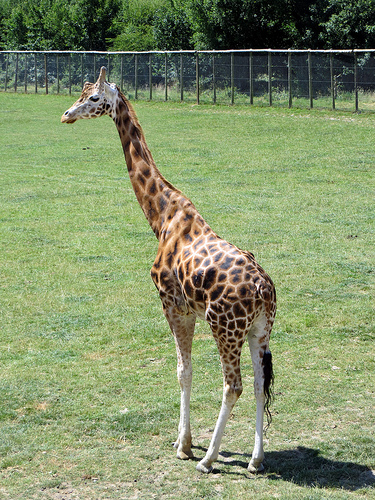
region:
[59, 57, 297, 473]
Giraffe with its neck extended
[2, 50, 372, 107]
Metal wire fence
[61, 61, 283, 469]
Brown and white giraffe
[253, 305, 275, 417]
Tail of the giraffe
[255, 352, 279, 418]
black hair of tail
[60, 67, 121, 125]
White and brown head of giraffe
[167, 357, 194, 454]
White front foot of elephant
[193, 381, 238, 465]
Left hind leg of giraffe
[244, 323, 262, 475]
right hind leg of giraffe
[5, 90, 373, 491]
green grassy area around giraffe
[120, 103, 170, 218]
long neck on a giraffe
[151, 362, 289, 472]
Long legs of a giraffe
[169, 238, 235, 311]
Brown and white giraffe patches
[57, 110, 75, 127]
Muzzle of a giraffe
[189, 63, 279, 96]
Fence in the background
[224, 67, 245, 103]
Pole on the fence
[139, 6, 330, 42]
Trees at the back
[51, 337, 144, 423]
Grass in the photo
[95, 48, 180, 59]
Bar on the fence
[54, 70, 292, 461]
Giraffe in the photo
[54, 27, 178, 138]
the head of a giraffe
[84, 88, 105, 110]
the eye of a giraffe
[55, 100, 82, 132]
the mouth of a giraffe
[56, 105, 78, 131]
the nose of a giraffe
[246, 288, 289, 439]
the tail of a giraffe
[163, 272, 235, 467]
the front legs of a giraffe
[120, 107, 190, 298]
the neck of a giraffe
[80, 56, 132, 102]
the ear of a giraffe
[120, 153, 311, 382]
the body of a giraffe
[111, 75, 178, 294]
the main of a giraffe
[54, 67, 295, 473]
giraffe standing in grass pasture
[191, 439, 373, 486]
giraffe's shadow on the grass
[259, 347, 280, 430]
black tail of the giraffe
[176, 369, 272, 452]
white legs of the giraffe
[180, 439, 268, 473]
hooves of the giraffe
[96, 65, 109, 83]
small furry horns on giraffe's head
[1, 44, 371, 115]
fencing along grass pasture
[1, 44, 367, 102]
wood posts fencing is attached to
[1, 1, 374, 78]
trees behind the fenceline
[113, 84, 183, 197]
mane of brown hair on giraffe's neck